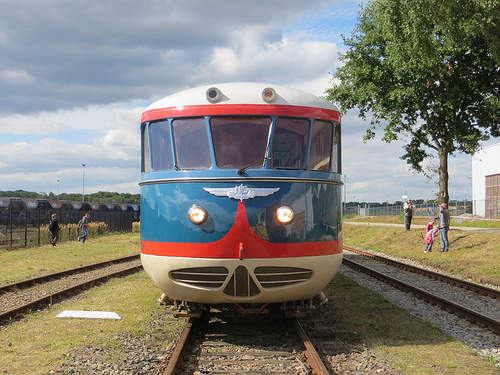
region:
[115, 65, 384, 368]
a train approaching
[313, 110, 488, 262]
people outside near the train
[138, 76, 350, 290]
train lights are on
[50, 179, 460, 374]
railroad tracks for the trains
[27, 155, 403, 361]
active train area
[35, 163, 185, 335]
people standing near the train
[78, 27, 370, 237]
overcast day with clouds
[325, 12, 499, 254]
tree with lots of leaves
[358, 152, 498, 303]
mom and daughter together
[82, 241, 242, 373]
rocks and grass mixed together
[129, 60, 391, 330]
a train facing the camera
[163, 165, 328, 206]
the logo of the train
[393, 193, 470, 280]
people watching the train move by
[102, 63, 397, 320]
a red and white and blue train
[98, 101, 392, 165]
the windows of the front of the train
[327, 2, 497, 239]
the big tree on the side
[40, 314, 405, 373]
the train tracks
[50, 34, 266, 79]
big clouds in the sky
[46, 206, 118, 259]
people running around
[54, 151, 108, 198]
the lamp post far away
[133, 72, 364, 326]
a white red and blue train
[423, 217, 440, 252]
a small child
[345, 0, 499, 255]
a tall green tree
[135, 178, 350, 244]
train lights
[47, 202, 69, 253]
a person leaning on the fence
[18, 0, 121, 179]
the cloudy gray sky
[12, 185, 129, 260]
two people leaning on a fence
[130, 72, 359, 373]
a train on railroad tracks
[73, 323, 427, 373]
rocky grass near a railroad track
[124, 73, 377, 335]
a large colorful train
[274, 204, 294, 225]
right white headlight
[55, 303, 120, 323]
piece of wood on the ground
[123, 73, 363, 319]
blue passenger train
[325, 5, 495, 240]
large green tree on the right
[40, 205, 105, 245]
two people left of the train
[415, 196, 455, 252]
parent and child near the tracks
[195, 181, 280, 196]
train company emblem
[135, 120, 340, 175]
non-reflective glass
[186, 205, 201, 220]
left front headlight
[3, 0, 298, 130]
overcast afternoon sky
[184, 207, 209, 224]
Left light that is turned on in the front of the train.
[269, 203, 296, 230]
Right light that is turned on in the front of the train.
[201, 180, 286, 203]
Silver wing design on the front of the train.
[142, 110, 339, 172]
The five windows on the front of the train.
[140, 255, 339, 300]
Beige design on the front of the train.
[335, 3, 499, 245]
Big green tree to the right of the train.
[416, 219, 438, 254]
Kid in pink jacket to the right of the train.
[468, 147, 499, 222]
White building on the right side.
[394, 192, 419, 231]
Person in black pants to the right of the train.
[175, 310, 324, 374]
Train tracks in front of the train.